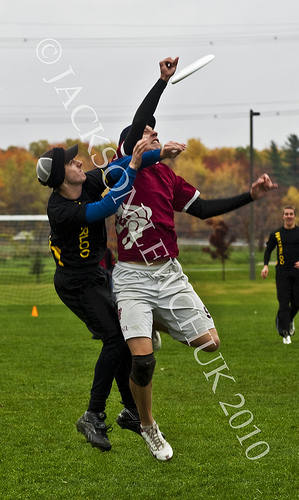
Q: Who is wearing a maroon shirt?
A: The player on the right trying to catch a Frisbee.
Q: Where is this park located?
A: In Chicago, IL.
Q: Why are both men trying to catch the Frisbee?
A: They're playing a game.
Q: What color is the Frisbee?
A: White.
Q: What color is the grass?
A: Green.